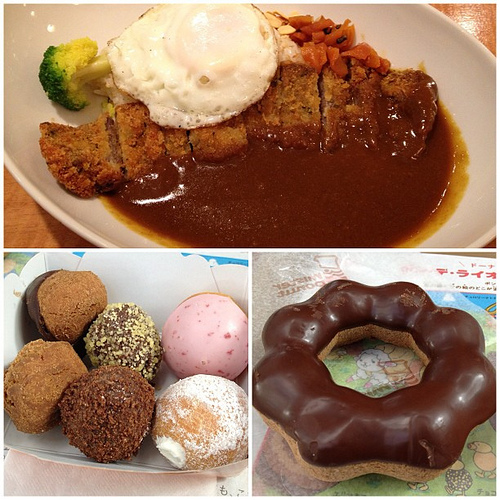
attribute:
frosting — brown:
[252, 280, 496, 467]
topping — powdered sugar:
[153, 374, 248, 468]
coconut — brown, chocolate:
[62, 367, 154, 462]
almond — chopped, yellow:
[84, 303, 166, 379]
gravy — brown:
[99, 60, 469, 248]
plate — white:
[0, 0, 497, 248]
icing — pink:
[163, 294, 249, 378]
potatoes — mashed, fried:
[108, 2, 279, 129]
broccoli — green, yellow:
[38, 37, 110, 110]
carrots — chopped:
[272, 16, 390, 79]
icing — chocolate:
[25, 269, 61, 340]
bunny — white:
[347, 349, 390, 392]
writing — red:
[434, 260, 498, 280]